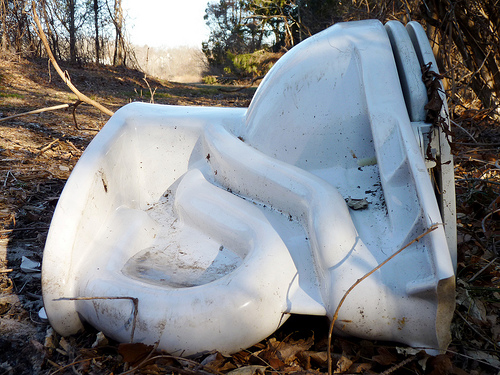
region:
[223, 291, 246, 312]
part of a toilet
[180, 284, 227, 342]
part of a toilet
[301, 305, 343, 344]
part of a stick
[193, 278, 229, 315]
edge of a toilet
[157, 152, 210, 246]
part of a toilet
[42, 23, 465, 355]
A toilet on the ground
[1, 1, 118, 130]
A branch on the ground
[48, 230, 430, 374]
some twigs under the toilet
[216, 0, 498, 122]
A large wooded area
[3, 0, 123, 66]
A wooded area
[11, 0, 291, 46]
A clear blue sky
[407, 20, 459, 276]
A toilet lid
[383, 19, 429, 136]
A toilet seat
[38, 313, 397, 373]
some leaves under the toilet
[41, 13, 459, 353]
an abandoned toilet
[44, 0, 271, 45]
Light blue sky in the background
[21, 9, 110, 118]
Curved light brown stick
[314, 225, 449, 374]
Curved light brown stick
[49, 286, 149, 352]
Small dirty stick crushed by toilet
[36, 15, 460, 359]
White porcelain toilet that's been tipped over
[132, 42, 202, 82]
Blurred trees in the background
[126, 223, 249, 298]
Dirty patch on the toilet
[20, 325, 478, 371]
Brown leaves underneath the toilet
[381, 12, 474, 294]
White toilet lid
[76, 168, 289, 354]
Curved portion of the toilet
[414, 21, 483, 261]
The lid on the toilet.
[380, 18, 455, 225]
The seat of the toilet.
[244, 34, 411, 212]
The basin area of the toilet.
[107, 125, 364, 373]
The piped shape area of the toilet.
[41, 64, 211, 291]
The bottom of the toilet.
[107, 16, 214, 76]
The trees in the far distance.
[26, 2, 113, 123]
The large branch to the left of the toilet.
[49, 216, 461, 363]
The small thin branches near the back of the toilet.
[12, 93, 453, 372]
The leaves on the ground.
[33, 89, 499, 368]
The area where the toilet is placed.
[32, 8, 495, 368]
Discarded toilet on forest trail.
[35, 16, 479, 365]
Porcelain toilet left in woods.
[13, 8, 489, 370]
Toilet left on hiking path.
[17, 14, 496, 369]
Toilet left in woods.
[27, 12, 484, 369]
Toilet left in forest.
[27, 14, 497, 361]
Toilet resting on leaves.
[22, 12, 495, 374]
Toilet discarded in woods.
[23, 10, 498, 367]
Porcelain toilet not properly disposed of.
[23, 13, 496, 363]
Commode left in woods.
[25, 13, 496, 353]
Porcelain throne left in forest.